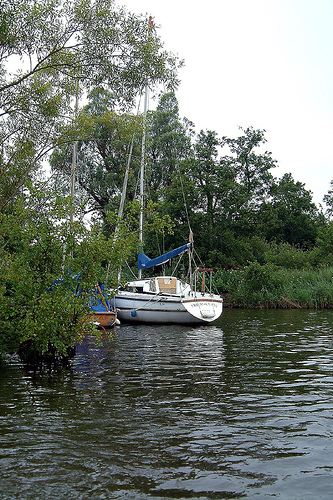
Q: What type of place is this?
A: It is a river.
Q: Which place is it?
A: It is a river.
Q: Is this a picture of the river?
A: Yes, it is showing the river.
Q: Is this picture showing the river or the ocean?
A: It is showing the river.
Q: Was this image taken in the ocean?
A: No, the picture was taken in the river.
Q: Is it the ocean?
A: No, it is the river.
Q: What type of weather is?
A: It is clear.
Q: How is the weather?
A: It is clear.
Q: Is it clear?
A: Yes, it is clear.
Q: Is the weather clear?
A: Yes, it is clear.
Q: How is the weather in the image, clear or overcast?
A: It is clear.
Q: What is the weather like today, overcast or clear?
A: It is clear.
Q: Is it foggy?
A: No, it is clear.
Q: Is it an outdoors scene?
A: Yes, it is outdoors.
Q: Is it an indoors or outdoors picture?
A: It is outdoors.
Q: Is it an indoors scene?
A: No, it is outdoors.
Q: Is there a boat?
A: Yes, there is a boat.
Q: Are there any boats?
A: Yes, there is a boat.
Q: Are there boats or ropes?
A: Yes, there is a boat.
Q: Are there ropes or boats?
A: Yes, there is a boat.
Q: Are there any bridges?
A: No, there are no bridges.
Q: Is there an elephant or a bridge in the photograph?
A: No, there are no bridges or elephants.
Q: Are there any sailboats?
A: Yes, there is a sailboat.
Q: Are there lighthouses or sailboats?
A: Yes, there is a sailboat.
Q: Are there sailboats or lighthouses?
A: Yes, there is a sailboat.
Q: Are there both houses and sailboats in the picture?
A: No, there is a sailboat but no houses.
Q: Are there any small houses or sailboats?
A: Yes, there is a small sailboat.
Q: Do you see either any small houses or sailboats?
A: Yes, there is a small sailboat.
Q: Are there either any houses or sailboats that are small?
A: Yes, the sailboat is small.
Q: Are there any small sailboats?
A: Yes, there is a small sailboat.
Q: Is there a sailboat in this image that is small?
A: Yes, there is a sailboat that is small.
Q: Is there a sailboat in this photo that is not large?
A: Yes, there is a small sailboat.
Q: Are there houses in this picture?
A: No, there are no houses.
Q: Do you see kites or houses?
A: No, there are no houses or kites.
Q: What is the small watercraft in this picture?
A: The watercraft is a sailboat.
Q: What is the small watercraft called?
A: The watercraft is a sailboat.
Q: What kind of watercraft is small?
A: The watercraft is a sailboat.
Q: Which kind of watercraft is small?
A: The watercraft is a sailboat.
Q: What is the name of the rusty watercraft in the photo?
A: The watercraft is a sailboat.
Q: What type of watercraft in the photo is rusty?
A: The watercraft is a sailboat.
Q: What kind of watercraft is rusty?
A: The watercraft is a sailboat.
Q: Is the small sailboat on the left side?
A: Yes, the sailboat is on the left of the image.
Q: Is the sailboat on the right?
A: No, the sailboat is on the left of the image.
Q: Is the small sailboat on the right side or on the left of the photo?
A: The sailboat is on the left of the image.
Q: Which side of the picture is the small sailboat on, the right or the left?
A: The sailboat is on the left of the image.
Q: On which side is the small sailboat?
A: The sailboat is on the left of the image.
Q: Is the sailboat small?
A: Yes, the sailboat is small.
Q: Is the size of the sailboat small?
A: Yes, the sailboat is small.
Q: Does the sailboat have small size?
A: Yes, the sailboat is small.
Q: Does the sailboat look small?
A: Yes, the sailboat is small.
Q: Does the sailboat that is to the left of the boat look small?
A: Yes, the sailboat is small.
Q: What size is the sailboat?
A: The sailboat is small.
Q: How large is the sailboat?
A: The sailboat is small.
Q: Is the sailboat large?
A: No, the sailboat is small.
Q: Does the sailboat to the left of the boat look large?
A: No, the sailboat is small.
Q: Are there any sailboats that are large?
A: No, there is a sailboat but it is small.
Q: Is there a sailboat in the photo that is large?
A: No, there is a sailboat but it is small.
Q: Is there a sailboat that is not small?
A: No, there is a sailboat but it is small.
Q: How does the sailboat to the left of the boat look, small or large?
A: The sailboat is small.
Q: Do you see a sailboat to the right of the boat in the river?
A: No, the sailboat is to the left of the boat.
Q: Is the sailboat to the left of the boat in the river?
A: Yes, the sailboat is to the left of the boat.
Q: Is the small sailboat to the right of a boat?
A: No, the sailboat is to the left of a boat.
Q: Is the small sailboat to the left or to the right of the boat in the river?
A: The sailboat is to the left of the boat.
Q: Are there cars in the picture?
A: No, there are no cars.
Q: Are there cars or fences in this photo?
A: No, there are no cars or fences.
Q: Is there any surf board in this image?
A: No, there are no surfboards.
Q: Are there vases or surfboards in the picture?
A: No, there are no surfboards or vases.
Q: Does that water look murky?
A: Yes, the water is murky.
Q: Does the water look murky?
A: Yes, the water is murky.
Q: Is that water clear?
A: No, the water is murky.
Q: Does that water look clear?
A: No, the water is murky.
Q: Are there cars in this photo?
A: No, there are no cars.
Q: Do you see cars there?
A: No, there are no cars.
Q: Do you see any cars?
A: No, there are no cars.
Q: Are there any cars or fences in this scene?
A: No, there are no cars or fences.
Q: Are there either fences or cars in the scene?
A: No, there are no cars or fences.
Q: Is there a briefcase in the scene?
A: No, there are no briefcases.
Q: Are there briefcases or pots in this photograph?
A: No, there are no briefcases or pots.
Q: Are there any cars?
A: No, there are no cars.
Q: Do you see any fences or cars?
A: No, there are no cars or fences.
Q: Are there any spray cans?
A: No, there are no spray cans.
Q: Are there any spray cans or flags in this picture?
A: No, there are no spray cans or flags.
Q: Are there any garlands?
A: No, there are no garlands.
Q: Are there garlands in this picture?
A: No, there are no garlands.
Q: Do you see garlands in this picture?
A: No, there are no garlands.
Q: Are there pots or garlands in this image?
A: No, there are no garlands or pots.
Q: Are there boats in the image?
A: Yes, there is a boat.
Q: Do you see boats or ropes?
A: Yes, there is a boat.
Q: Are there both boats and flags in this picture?
A: No, there is a boat but no flags.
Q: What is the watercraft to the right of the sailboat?
A: The watercraft is a boat.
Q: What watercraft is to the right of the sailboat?
A: The watercraft is a boat.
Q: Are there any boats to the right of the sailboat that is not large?
A: Yes, there is a boat to the right of the sailboat.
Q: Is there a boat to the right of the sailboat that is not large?
A: Yes, there is a boat to the right of the sailboat.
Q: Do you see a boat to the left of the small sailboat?
A: No, the boat is to the right of the sailboat.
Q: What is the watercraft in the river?
A: The watercraft is a boat.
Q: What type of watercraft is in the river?
A: The watercraft is a boat.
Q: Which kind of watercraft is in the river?
A: The watercraft is a boat.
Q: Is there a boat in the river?
A: Yes, there is a boat in the river.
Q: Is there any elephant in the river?
A: No, there is a boat in the river.